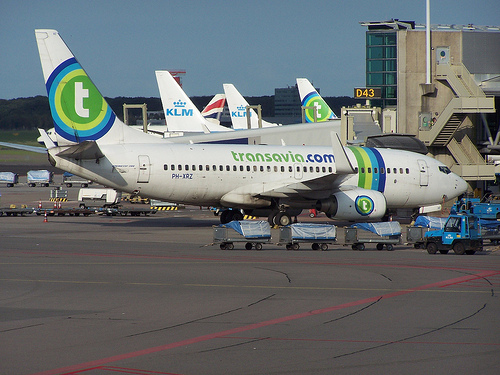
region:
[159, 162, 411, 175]
row of airplane passenger windows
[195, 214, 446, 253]
row of luggage carts being towed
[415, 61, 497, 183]
three flights of concrete stairs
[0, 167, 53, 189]
two covered luggage carts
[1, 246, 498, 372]
painted traffic lanes on airfield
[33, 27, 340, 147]
four airplane tail fins with logos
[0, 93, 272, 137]
line of low hills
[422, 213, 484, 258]
airport towing vehicle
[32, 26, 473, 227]
passenger plane parked on tarmac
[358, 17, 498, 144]
six floor airport building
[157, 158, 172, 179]
Small window on a plane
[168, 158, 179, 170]
Small window on a plane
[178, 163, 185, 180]
Small window on a plane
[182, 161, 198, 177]
Small window on a plane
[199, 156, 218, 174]
Small window on a plane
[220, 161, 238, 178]
Small window on a plane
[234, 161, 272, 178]
Small window on a plane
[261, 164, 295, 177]
Small window on a plane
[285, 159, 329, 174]
Small window on a plane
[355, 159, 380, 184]
Small window on a plane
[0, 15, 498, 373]
White planes outside of an airport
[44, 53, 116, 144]
Large circular blue and green logo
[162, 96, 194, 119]
Blue logo on an airplane fin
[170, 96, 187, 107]
Blue crown logo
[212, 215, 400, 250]
Three luggage carts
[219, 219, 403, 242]
Three silver and blue luggage tarps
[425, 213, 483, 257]
Small blue airport vehicle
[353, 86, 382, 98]
Black digital sign with orange lights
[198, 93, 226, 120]
Red and blue stripe on an airplane fin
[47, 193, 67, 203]
Yellow and black caution paint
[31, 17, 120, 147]
one blue and green airplane tail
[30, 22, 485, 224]
several airplanes lined up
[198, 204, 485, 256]
line of baggage carts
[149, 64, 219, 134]
white KLM airplane tail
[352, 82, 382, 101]
yellow lettered D43 sign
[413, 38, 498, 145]
light colored metal stairs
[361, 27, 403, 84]
large rectangular shaped building windows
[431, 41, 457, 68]
one gray metal door with round window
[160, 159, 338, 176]
row of dark oval airplane windows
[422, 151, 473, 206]
front of large white airplane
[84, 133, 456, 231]
airplane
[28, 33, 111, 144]
tail of airplane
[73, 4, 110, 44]
white clouds in blue sky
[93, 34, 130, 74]
white clouds in blue sky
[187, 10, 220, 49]
white clouds in blue sky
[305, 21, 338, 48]
white clouds in blue sky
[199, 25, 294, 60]
white clouds in blue sky